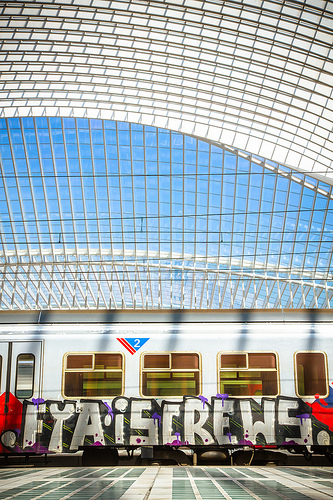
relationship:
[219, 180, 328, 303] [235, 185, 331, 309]
part of the sky. part of sky part of the sky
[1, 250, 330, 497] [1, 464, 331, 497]
train station has floor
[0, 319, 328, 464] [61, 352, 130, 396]
train has window of  train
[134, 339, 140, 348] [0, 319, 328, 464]
number 2 on train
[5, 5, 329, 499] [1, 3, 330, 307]
train terminal has top of terminal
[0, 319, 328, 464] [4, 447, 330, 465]
train has bottom of train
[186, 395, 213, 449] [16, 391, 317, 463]
letter "r" on graffiti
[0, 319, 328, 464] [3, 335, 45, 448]
train has door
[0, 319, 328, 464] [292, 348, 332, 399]
train has back window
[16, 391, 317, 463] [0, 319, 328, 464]
graffiti on train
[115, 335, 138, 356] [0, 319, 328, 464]
two red stripes on train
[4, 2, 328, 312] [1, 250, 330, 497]
glass roof in train station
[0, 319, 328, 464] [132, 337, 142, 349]
train color 2 is white